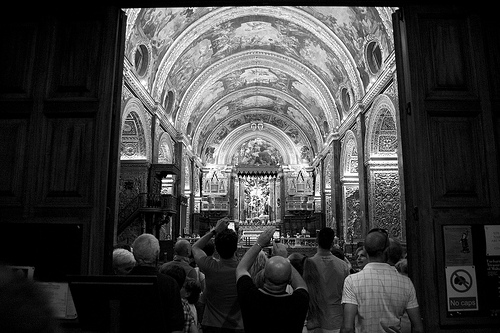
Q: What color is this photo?
A: Black and white.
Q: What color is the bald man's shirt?
A: Black.